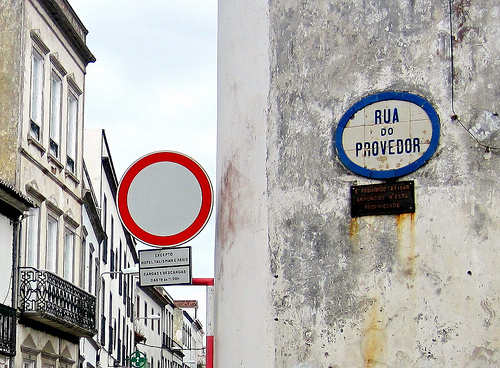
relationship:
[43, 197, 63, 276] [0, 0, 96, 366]
window on building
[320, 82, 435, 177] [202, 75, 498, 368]
plaque on wall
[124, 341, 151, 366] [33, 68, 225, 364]
sign on building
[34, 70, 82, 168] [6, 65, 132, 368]
window on building